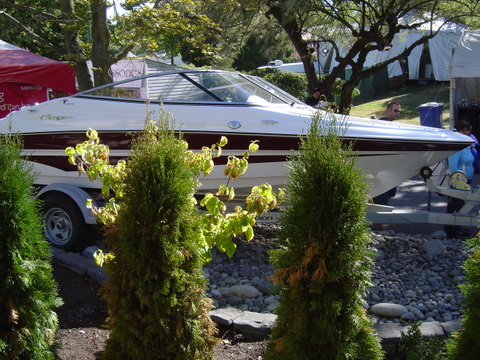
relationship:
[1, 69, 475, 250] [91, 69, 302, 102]
boat has window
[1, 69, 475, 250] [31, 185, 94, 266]
boat has wheel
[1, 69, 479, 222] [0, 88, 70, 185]
boat has back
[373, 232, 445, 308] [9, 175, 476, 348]
rocks in driveway